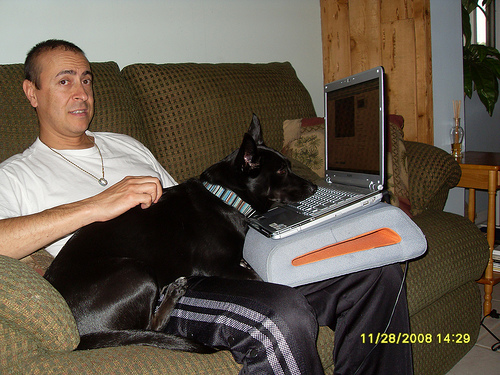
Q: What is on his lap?
A: Dog.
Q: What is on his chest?
A: Necklace.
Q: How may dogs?
A: One.